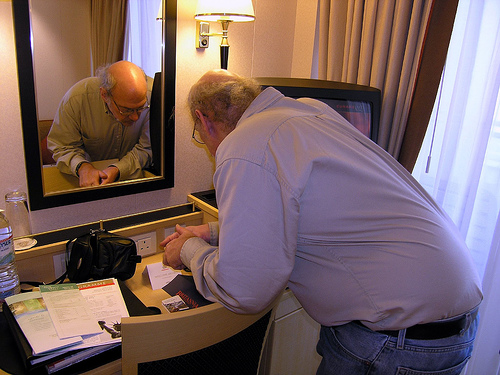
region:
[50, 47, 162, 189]
mans reflection in the mirror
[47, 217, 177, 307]
mans to go bag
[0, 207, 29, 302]
water bottle on the side of the desk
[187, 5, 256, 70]
lamp above the mans head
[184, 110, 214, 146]
the man is wearing glasses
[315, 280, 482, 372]
the man is wearing blue jeans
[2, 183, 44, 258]
a clean glass cup on the side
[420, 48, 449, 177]
curtain adjustment tool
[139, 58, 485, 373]
man in hotel room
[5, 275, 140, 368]
white brochures on the desk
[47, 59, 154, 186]
reflection of balding man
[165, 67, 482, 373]
mature man wearing purple shirt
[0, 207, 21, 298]
water bottle on desk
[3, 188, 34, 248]
glass upside down on desk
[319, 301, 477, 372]
black belt on blue jeans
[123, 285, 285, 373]
black and brown wood chair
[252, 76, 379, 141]
old tube tv behind man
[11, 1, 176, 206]
mirror with a black frame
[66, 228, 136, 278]
black camera bag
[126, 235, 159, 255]
white outlet on desk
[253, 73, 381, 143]
TV monitor behind the man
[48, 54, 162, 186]
man's reflection in mirror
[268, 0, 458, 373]
beige curtain behind television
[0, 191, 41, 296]
empty glass cup next to water bottle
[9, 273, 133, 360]
pile of brochures and papers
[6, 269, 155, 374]
black binder under pile of brochures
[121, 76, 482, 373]
man leans on wooden chair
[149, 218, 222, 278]
man's hands are clasped in front of him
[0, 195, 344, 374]
light wood desk and matching chair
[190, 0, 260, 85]
lamp attached to mauve-colored wall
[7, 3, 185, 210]
A man's reflection in a mirror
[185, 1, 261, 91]
A wall lamp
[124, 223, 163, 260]
An electrical outlet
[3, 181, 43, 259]
An empty glass upside-down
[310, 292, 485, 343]
a man's belt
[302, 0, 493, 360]
A partially open curtain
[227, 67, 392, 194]
a TV in the corner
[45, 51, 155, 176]
A man wearing glasses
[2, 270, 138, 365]
3 or more brochures on a desk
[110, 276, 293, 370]
a chair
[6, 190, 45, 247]
empty glass sitting on table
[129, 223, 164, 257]
white electric outlet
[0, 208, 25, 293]
plastic water bottle sitting on table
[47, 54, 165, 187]
reflection of man in mirror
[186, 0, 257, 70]
gold and black lamp on wall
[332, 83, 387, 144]
large CRT tv monitor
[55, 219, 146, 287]
small black camera bag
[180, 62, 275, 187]
balding man in glasses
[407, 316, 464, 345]
black belt on man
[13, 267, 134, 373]
books laying on table